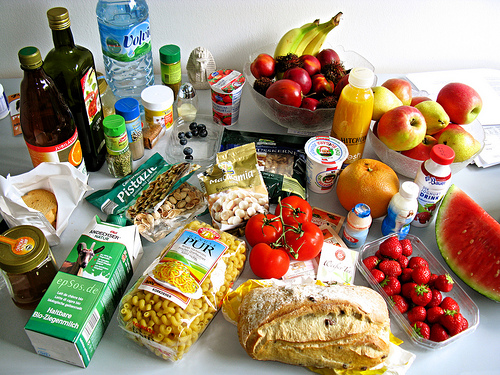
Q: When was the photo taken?
A: Daytime.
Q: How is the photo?
A: Clear.